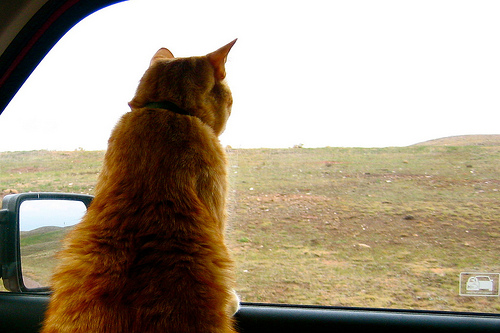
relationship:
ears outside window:
[139, 19, 277, 83] [23, 9, 487, 305]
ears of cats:
[139, 19, 277, 83] [84, 43, 252, 323]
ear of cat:
[153, 46, 172, 65] [39, 36, 238, 329]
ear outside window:
[153, 46, 172, 65] [3, 4, 498, 316]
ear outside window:
[149, 47, 174, 66] [3, 4, 498, 316]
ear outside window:
[189, 29, 269, 109] [3, 4, 498, 316]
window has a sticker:
[3, 4, 498, 316] [459, 271, 498, 299]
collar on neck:
[131, 97, 194, 118] [122, 93, 223, 155]